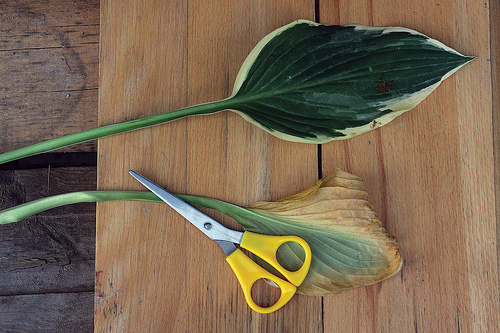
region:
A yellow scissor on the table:
[124, 163, 315, 330]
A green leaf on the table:
[0, 17, 480, 177]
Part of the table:
[426, 145, 483, 223]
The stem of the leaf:
[2, 94, 233, 168]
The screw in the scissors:
[201, 220, 216, 233]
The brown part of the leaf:
[311, 190, 347, 217]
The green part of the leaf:
[327, 236, 344, 266]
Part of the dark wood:
[26, 235, 62, 256]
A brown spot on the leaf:
[369, 70, 398, 98]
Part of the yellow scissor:
[237, 258, 242, 270]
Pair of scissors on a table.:
[128, 169, 311, 314]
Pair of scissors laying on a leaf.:
[128, 168, 312, 313]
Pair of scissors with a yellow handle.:
[128, 168, 310, 313]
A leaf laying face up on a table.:
[2, 19, 479, 166]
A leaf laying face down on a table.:
[0, 165, 403, 295]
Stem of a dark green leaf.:
[0, 96, 229, 163]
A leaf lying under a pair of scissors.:
[0, 165, 401, 290]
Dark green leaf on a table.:
[0, 17, 472, 163]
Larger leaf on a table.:
[0, 17, 476, 164]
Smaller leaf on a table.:
[0, 166, 403, 295]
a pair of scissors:
[126, 168, 313, 313]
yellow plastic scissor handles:
[227, 228, 313, 313]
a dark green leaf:
[223, 17, 477, 154]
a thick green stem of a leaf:
[2, 93, 227, 166]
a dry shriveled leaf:
[242, 168, 404, 305]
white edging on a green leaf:
[227, 16, 474, 145]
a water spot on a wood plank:
[0, 8, 85, 146]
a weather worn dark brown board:
[0, 159, 99, 329]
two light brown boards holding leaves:
[95, 0, 499, 332]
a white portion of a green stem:
[4, 186, 91, 225]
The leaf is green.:
[123, 1, 476, 160]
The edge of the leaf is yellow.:
[200, 14, 465, 161]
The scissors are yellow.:
[111, 159, 321, 320]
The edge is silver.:
[120, 154, 235, 257]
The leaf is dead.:
[202, 179, 417, 309]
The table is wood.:
[97, 2, 496, 332]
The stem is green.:
[5, 84, 227, 169]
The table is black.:
[0, 0, 95, 317]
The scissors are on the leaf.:
[8, 11, 488, 331]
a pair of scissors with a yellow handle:
[120, 165, 314, 320]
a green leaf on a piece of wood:
[3, 5, 480, 181]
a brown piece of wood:
[97, 3, 499, 327]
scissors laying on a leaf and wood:
[117, 159, 318, 319]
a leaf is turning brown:
[230, 166, 412, 301]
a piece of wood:
[1, 2, 99, 155]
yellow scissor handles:
[216, 226, 316, 318]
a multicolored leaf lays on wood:
[215, 6, 480, 152]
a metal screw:
[201, 218, 215, 233]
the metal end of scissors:
[121, 161, 248, 258]